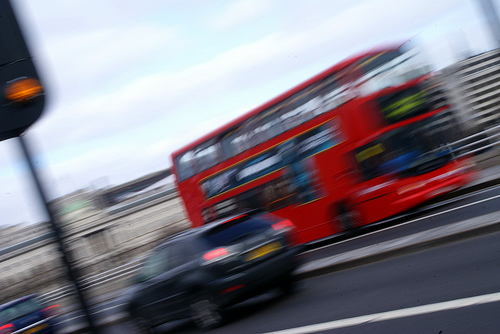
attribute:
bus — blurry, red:
[172, 44, 475, 246]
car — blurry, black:
[122, 208, 299, 333]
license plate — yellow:
[247, 241, 281, 262]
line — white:
[261, 293, 499, 332]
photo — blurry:
[2, 3, 498, 333]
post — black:
[18, 136, 102, 333]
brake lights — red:
[273, 218, 294, 232]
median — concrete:
[293, 211, 497, 278]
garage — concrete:
[2, 166, 192, 295]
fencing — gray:
[440, 124, 499, 163]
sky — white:
[2, 3, 497, 223]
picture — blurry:
[1, 3, 498, 333]